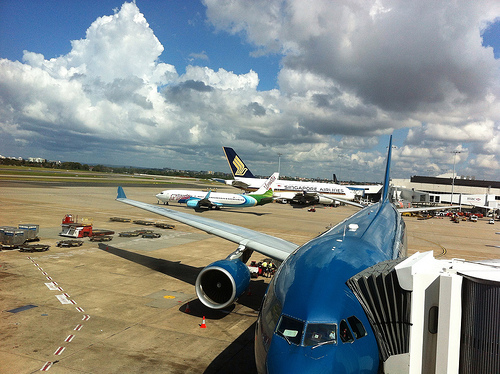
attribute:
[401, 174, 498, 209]
building — tan, black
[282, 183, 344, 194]
lettering — black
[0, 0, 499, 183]
clouds — thick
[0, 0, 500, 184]
sky — blue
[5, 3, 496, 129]
clouds — white 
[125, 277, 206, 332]
spot — yellow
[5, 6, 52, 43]
sky — blue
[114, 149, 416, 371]
plane — blue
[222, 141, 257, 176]
plane part — yellow, black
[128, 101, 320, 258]
plane — white, blue, green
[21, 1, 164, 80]
cloud — white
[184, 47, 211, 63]
cloud — white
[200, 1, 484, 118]
cloud — white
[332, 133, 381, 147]
cloud — white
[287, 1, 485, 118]
cloud — white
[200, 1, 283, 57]
cloud — white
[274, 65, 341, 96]
cloud — white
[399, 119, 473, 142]
cloud — white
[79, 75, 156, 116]
cloud — white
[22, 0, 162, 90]
cloud — white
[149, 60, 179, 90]
cloud — white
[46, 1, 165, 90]
cloud — white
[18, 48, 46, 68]
cloud — white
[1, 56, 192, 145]
cloud — white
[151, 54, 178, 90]
cloud — white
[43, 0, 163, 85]
cloud — white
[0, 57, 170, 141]
cloud — white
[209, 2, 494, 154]
clouds — white